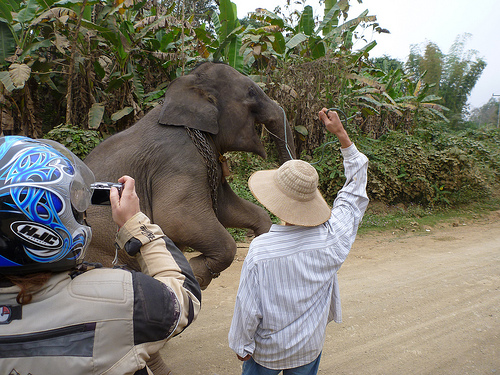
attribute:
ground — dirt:
[164, 212, 497, 373]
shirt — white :
[226, 141, 369, 371]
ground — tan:
[404, 268, 481, 373]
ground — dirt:
[398, 268, 480, 368]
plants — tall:
[0, 0, 488, 167]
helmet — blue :
[2, 127, 104, 279]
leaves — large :
[25, 3, 127, 73]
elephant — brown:
[133, 75, 247, 220]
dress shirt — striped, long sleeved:
[229, 139, 369, 367]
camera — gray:
[82, 177, 121, 205]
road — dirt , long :
[383, 226, 498, 365]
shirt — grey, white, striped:
[223, 147, 383, 372]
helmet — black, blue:
[0, 135, 91, 272]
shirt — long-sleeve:
[230, 230, 345, 365]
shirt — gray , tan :
[218, 216, 378, 373]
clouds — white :
[361, 7, 416, 57]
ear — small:
[161, 67, 218, 135]